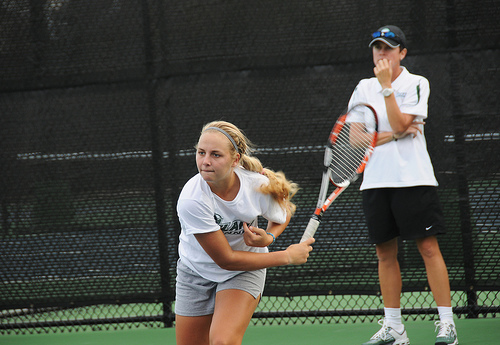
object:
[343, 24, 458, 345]
man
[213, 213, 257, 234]
logo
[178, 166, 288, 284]
shirt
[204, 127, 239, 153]
headband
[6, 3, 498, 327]
net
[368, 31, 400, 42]
glasses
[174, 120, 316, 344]
lady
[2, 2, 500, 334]
fence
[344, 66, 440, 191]
shirt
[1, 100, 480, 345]
tennis game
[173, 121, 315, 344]
girl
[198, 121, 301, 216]
hair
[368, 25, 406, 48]
baseball cap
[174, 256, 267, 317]
shorts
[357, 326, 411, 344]
shoe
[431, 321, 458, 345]
shoe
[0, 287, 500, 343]
court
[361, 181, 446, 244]
shorts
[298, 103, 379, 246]
racket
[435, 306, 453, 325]
socks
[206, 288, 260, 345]
thighs